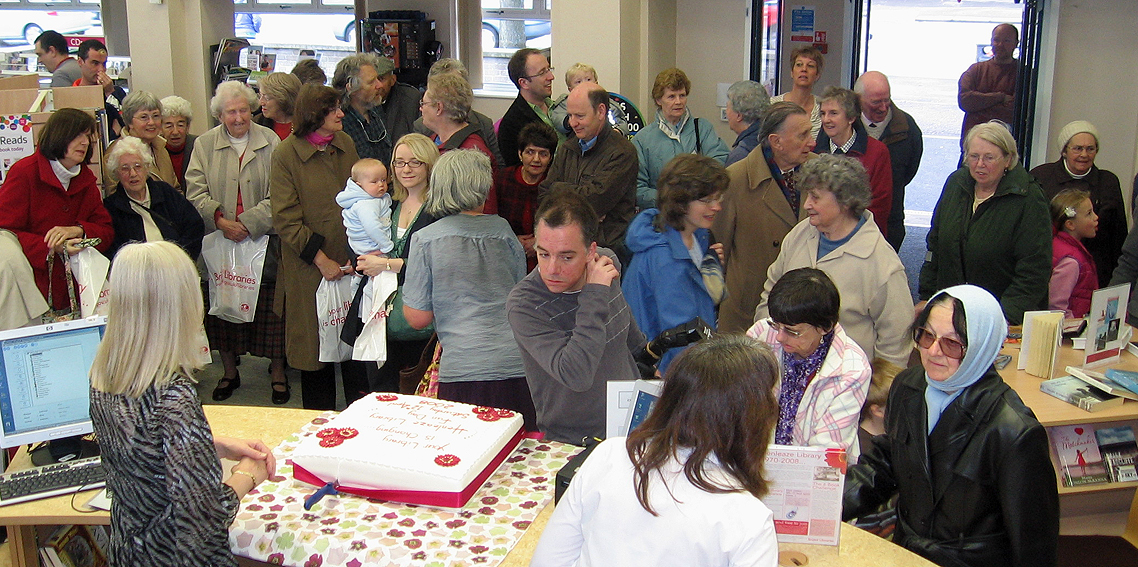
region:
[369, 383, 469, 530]
A person eating a orange.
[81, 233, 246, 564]
woman with blonde hair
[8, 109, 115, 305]
woman in a red coat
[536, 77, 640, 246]
man with a bald head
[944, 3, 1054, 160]
man leaning against a wall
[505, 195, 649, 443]
man touching his ear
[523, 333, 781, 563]
woman in a white shirt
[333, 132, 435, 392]
the woman is carrying a baby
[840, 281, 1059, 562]
the woman is wearing a black jacket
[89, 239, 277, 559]
the woman has white hair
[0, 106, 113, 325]
the woman wearing a red jacket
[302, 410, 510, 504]
red and white cake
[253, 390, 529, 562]
white mat under cake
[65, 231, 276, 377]
woman has white hair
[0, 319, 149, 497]
monitor next to woman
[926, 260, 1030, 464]
woman has blue scarf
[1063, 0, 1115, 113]
tan wall behind people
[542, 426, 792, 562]
woman has white shirt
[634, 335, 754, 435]
woman has brown hair at table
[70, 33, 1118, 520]
a meeting in the background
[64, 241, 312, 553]
blond hair on the woman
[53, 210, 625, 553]
wooden desk in the background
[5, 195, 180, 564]
computer on the desk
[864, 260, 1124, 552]
person wearing a black coat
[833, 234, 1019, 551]
person with a blue scarf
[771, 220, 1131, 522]
person wearing glasses